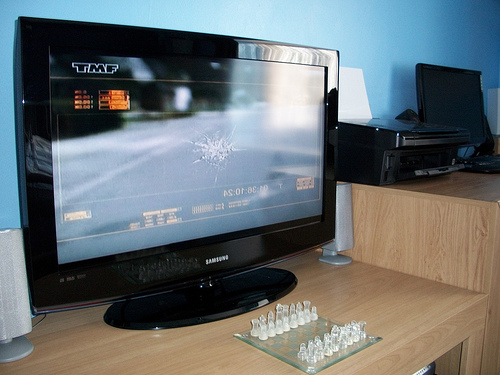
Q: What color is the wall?
A: Blue.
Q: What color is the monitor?
A: Black.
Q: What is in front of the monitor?
A: Chess game.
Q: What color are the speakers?
A: Gray.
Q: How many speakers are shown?
A: Two.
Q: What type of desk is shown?
A: Wooden.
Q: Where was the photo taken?
A: In a house.